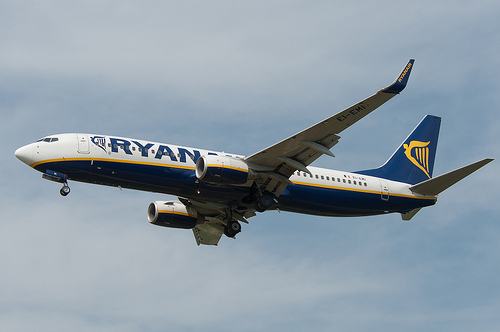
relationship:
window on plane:
[72, 129, 130, 157] [15, 79, 497, 280]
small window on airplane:
[315, 173, 323, 178] [10, 57, 499, 249]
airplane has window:
[10, 57, 499, 249] [104, 141, 111, 146]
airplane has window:
[10, 57, 499, 249] [306, 173, 316, 176]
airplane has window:
[10, 57, 499, 249] [130, 145, 137, 152]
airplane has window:
[10, 57, 499, 249] [131, 145, 136, 151]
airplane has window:
[10, 57, 499, 249] [149, 148, 158, 158]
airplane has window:
[10, 57, 499, 249] [311, 157, 388, 204]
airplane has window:
[10, 57, 499, 249] [360, 179, 370, 189]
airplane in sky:
[10, 57, 499, 249] [2, 2, 499, 330]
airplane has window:
[10, 57, 499, 249] [363, 180, 368, 185]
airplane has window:
[10, 57, 499, 249] [346, 175, 351, 187]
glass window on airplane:
[346, 176, 353, 188] [20, 97, 450, 223]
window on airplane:
[336, 175, 341, 182] [10, 57, 499, 249]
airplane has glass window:
[22, 85, 447, 267] [298, 171, 308, 181]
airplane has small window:
[10, 57, 499, 249] [324, 174, 331, 182]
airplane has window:
[10, 57, 499, 249] [298, 167, 308, 179]